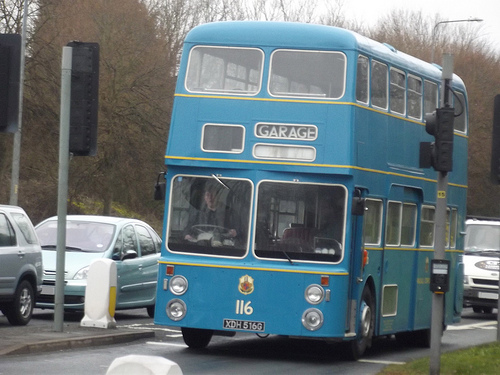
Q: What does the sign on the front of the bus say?
A: Garage.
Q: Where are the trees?
A: Behind the bus and cars.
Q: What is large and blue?
A: The bus.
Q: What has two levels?
A: The bus.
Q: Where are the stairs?
A: Inside the bus.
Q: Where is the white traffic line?
A: In the street.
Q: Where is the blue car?
A: Next to the bus.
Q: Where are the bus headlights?
A: On the front.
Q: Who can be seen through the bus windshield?
A: The driver.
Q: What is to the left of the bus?
A: A blue car.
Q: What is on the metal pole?
A: A black sign.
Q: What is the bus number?
A: 116.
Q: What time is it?
A: Afternoon.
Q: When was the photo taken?
A: During the daytime.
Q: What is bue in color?
A: The bus.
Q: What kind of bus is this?
A: Double decker bus.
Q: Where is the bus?
A: In the road.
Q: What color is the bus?
A: Blue.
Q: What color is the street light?
A: Black.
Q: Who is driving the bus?
A: The bus driver.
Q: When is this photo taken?
A: During the day.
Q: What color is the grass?
A: Green.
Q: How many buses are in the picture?
A: One.